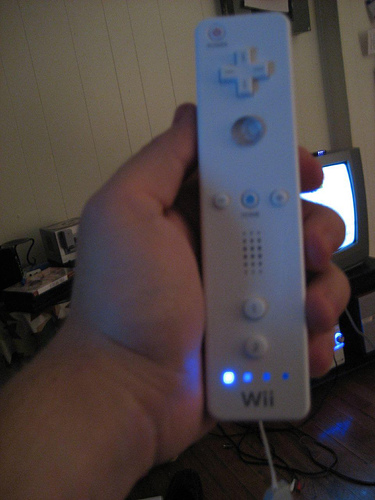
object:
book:
[0, 260, 73, 353]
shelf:
[0, 237, 88, 389]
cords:
[210, 417, 375, 500]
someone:
[0, 101, 350, 498]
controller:
[190, 14, 311, 423]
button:
[203, 19, 281, 358]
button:
[268, 188, 291, 206]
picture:
[0, 0, 375, 500]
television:
[296, 144, 371, 264]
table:
[2, 218, 85, 381]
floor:
[119, 347, 375, 500]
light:
[299, 161, 358, 256]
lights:
[222, 370, 234, 386]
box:
[41, 215, 80, 270]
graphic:
[240, 388, 275, 409]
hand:
[72, 102, 350, 459]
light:
[240, 370, 253, 382]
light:
[263, 371, 271, 380]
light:
[281, 372, 288, 380]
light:
[332, 331, 344, 349]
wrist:
[42, 334, 146, 484]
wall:
[0, 0, 375, 261]